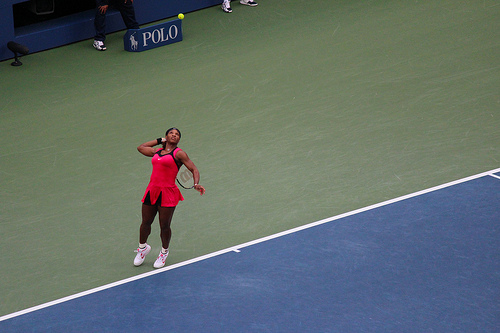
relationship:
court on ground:
[0, 169, 499, 331] [2, 2, 497, 331]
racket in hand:
[172, 154, 209, 207] [192, 174, 208, 201]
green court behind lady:
[135, 50, 462, 125] [131, 126, 206, 271]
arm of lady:
[180, 152, 200, 182] [131, 126, 206, 271]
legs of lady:
[136, 199, 176, 251] [131, 126, 206, 271]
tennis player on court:
[118, 117, 215, 290] [0, 0, 498, 330]